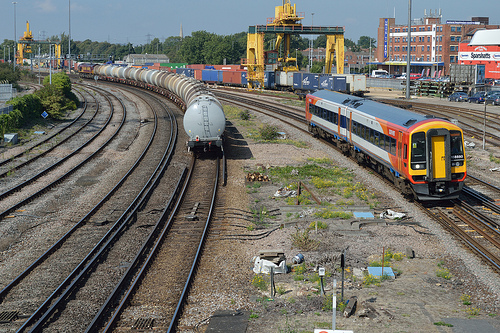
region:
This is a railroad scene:
[1, 0, 498, 330]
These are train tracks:
[0, 71, 229, 330]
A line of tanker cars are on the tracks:
[94, 59, 231, 154]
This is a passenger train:
[304, 85, 468, 205]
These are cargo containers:
[152, 57, 369, 96]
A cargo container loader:
[244, 0, 348, 94]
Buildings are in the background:
[347, 10, 498, 85]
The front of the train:
[409, 120, 468, 202]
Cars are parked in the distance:
[446, 88, 498, 106]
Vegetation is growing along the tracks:
[2, 71, 77, 132]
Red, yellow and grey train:
[291, 78, 475, 213]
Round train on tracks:
[104, 60, 236, 164]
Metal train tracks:
[104, 164, 226, 330]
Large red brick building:
[366, 3, 458, 81]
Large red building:
[449, 21, 499, 77]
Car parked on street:
[447, 87, 472, 106]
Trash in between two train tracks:
[348, 198, 417, 235]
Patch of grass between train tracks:
[267, 146, 370, 196]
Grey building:
[121, 48, 171, 66]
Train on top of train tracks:
[299, 81, 483, 208]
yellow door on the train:
[426, 134, 452, 186]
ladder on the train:
[199, 98, 212, 138]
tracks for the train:
[0, 73, 240, 332]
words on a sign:
[456, 43, 498, 70]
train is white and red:
[301, 91, 414, 178]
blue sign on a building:
[377, 16, 396, 63]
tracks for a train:
[208, 73, 498, 318]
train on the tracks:
[294, 76, 477, 237]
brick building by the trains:
[377, 16, 497, 70]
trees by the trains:
[151, 23, 254, 67]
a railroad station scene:
[0, 0, 493, 325]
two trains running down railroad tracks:
[0, 2, 498, 324]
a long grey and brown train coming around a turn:
[81, 63, 251, 164]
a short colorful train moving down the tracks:
[303, 80, 470, 205]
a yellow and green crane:
[232, 0, 350, 92]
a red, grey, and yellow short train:
[301, 86, 470, 206]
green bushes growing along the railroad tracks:
[0, 69, 82, 131]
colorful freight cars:
[177, 60, 364, 91]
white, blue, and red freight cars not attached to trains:
[189, 57, 364, 91]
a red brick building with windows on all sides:
[373, 5, 490, 72]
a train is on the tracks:
[298, 81, 472, 207]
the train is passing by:
[306, 83, 470, 204]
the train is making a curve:
[300, 83, 467, 204]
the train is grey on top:
[311, 84, 444, 126]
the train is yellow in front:
[405, 120, 467, 187]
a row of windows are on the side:
[306, 102, 405, 153]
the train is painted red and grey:
[304, 89, 422, 173]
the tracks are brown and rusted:
[231, 88, 491, 273]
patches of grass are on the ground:
[246, 154, 385, 224]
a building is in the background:
[376, 11, 499, 81]